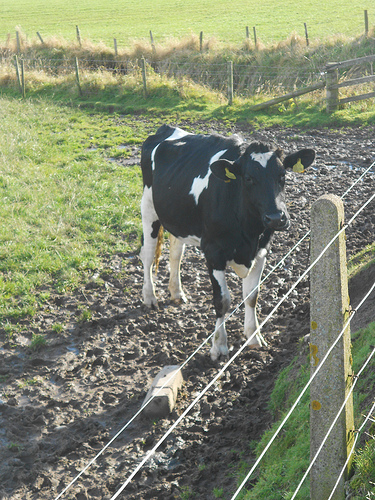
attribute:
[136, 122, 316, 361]
cow — standing, white, black, looking forward, inside barnyard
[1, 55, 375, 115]
fence — wire, wire cable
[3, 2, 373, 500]
ground — dirty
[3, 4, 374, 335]
grass — uncut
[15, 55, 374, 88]
wires — metal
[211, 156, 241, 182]
ear — round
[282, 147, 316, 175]
ear — round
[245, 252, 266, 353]
leg — white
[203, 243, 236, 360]
leg — black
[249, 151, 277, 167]
spot — white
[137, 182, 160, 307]
back leg — white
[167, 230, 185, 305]
back leg — white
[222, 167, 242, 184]
tag — yellow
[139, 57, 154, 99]
fence post — wooden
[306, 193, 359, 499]
fence post — concrete